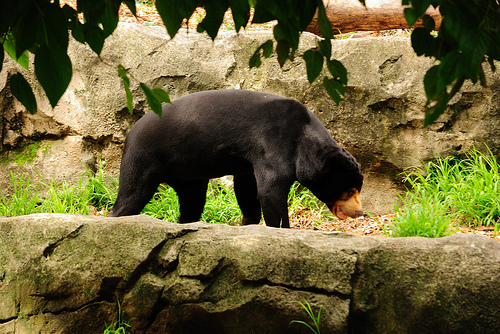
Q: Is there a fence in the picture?
A: No, there are no fences.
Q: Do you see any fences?
A: No, there are no fences.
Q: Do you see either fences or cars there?
A: No, there are no fences or cars.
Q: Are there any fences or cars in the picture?
A: No, there are no fences or cars.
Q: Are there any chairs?
A: No, there are no chairs.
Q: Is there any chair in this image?
A: No, there are no chairs.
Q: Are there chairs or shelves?
A: No, there are no chairs or shelves.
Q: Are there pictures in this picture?
A: No, there are no pictures.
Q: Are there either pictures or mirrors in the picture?
A: No, there are no pictures or mirrors.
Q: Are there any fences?
A: No, there are no fences.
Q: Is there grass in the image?
A: Yes, there is grass.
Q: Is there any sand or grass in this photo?
A: Yes, there is grass.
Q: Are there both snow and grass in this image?
A: No, there is grass but no snow.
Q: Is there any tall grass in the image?
A: Yes, there is tall grass.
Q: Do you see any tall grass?
A: Yes, there is tall grass.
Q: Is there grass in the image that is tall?
A: Yes, there is grass that is tall.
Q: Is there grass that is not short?
A: Yes, there is tall grass.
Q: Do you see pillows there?
A: No, there are no pillows.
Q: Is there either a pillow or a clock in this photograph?
A: No, there are no pillows or clocks.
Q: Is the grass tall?
A: Yes, the grass is tall.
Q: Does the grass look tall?
A: Yes, the grass is tall.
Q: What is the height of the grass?
A: The grass is tall.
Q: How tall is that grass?
A: The grass is tall.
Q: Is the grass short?
A: No, the grass is tall.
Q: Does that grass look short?
A: No, the grass is tall.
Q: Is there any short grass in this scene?
A: No, there is grass but it is tall.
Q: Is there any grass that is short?
A: No, there is grass but it is tall.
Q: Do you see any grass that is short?
A: No, there is grass but it is tall.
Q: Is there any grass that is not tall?
A: No, there is grass but it is tall.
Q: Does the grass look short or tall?
A: The grass is tall.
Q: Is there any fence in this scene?
A: No, there are no fences.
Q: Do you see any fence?
A: No, there are no fences.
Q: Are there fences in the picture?
A: No, there are no fences.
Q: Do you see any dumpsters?
A: No, there are no dumpsters.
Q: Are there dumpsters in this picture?
A: No, there are no dumpsters.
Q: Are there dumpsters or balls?
A: No, there are no dumpsters or balls.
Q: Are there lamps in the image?
A: No, there are no lamps.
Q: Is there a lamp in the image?
A: No, there are no lamps.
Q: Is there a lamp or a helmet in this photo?
A: No, there are no lamps or helmets.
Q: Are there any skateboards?
A: No, there are no skateboards.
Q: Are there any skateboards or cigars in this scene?
A: No, there are no skateboards or cigars.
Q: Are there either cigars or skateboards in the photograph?
A: No, there are no skateboards or cigars.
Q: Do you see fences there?
A: No, there are no fences.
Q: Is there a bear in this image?
A: Yes, there is a bear.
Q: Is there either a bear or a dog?
A: Yes, there is a bear.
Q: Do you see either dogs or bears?
A: Yes, there is a bear.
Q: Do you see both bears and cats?
A: No, there is a bear but no cats.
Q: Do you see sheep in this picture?
A: No, there are no sheep.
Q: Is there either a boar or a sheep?
A: No, there are no sheep or boars.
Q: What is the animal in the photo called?
A: The animal is a bear.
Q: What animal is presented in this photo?
A: The animal is a bear.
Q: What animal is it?
A: The animal is a bear.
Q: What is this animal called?
A: This is a bear.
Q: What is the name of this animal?
A: This is a bear.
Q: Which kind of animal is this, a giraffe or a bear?
A: This is a bear.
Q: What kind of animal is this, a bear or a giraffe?
A: This is a bear.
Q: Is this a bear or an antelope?
A: This is a bear.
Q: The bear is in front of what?
A: The bear is in front of the wall.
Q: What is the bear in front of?
A: The bear is in front of the wall.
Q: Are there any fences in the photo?
A: No, there are no fences.